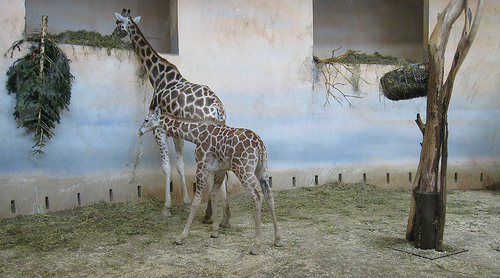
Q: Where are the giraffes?
A: Along the wall.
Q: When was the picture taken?
A: Day time.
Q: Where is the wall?
A: Front of giraffes.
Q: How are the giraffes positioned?
A: Standing.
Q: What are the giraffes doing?
A: Eating.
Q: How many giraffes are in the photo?
A: 2.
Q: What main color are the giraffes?
A: Brown.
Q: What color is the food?
A: Green.